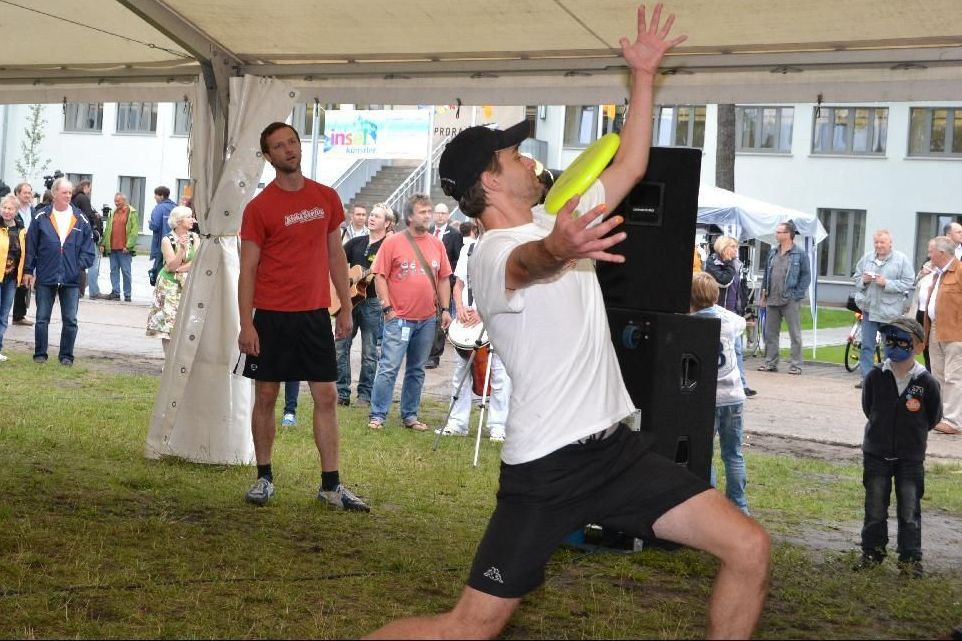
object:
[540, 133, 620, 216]
frisbee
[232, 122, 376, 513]
man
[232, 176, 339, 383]
clothing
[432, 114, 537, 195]
cap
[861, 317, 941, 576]
boy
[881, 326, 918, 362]
face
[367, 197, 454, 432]
man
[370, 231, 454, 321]
shirt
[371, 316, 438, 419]
jeans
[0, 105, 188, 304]
wall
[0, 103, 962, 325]
building